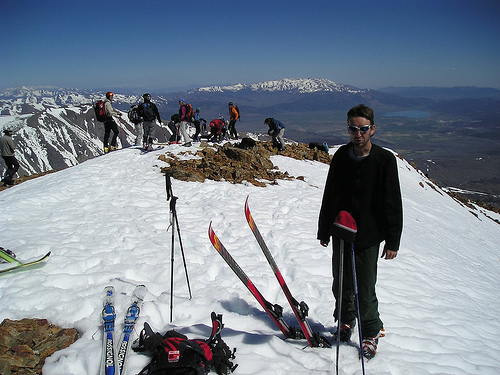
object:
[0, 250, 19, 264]
ski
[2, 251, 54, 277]
ski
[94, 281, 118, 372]
ski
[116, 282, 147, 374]
ski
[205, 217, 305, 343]
ski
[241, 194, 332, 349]
ski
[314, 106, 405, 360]
man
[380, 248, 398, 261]
hand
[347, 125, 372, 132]
glasses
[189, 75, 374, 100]
mountain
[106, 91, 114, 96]
helmet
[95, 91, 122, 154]
man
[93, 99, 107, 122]
backpack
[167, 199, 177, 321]
ski pole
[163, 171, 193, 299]
ski pole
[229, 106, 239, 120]
jacket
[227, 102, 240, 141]
man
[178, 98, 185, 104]
hat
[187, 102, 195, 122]
backpack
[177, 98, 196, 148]
man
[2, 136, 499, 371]
moutain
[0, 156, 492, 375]
snow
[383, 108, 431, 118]
lake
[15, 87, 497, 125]
background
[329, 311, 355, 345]
ski boot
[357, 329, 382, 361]
ski boot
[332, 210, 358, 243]
hat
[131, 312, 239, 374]
backpack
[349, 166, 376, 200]
part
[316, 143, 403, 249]
coat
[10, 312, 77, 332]
edge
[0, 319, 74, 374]
rock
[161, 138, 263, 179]
part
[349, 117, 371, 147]
face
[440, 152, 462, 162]
part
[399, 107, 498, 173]
plain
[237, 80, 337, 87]
snow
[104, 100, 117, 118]
jacket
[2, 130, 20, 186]
person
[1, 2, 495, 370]
shot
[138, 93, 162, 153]
person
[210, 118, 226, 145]
person